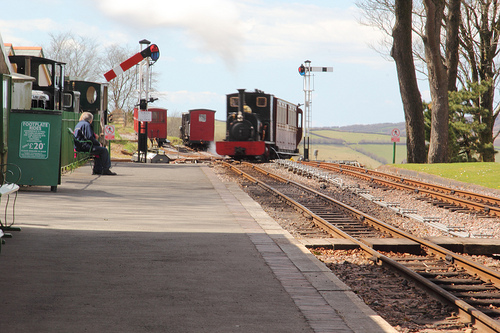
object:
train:
[213, 88, 301, 162]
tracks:
[203, 149, 496, 332]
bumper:
[215, 141, 265, 156]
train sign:
[100, 43, 152, 83]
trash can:
[7, 108, 58, 192]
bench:
[66, 127, 94, 172]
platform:
[0, 162, 394, 333]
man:
[74, 112, 118, 175]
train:
[180, 108, 217, 149]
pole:
[137, 37, 150, 162]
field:
[98, 115, 500, 190]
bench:
[1, 148, 23, 240]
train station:
[0, 40, 402, 333]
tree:
[389, 0, 428, 162]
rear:
[189, 108, 216, 143]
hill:
[291, 122, 408, 164]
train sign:
[295, 64, 332, 73]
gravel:
[208, 159, 500, 330]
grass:
[388, 162, 499, 191]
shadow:
[0, 227, 458, 333]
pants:
[79, 145, 112, 172]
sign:
[138, 110, 153, 122]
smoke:
[91, 0, 242, 85]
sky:
[0, 0, 488, 128]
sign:
[390, 126, 402, 142]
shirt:
[73, 121, 93, 141]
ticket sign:
[18, 120, 51, 161]